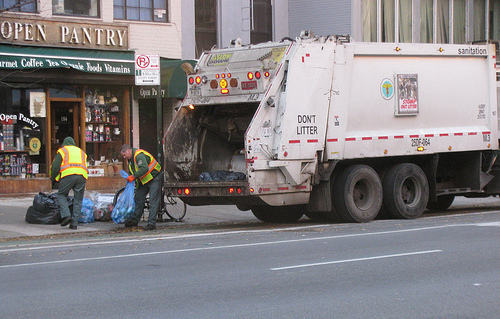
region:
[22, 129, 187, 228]
two men collecting garbage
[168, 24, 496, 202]
white garbage truck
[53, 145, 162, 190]
men wearing orange and yellow safety vests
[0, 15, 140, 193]
coffe shop in the building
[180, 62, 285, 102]
yellow and red lights on back of truck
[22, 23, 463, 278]
picture taken on a city street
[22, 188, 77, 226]
black garbage bags on sidewalk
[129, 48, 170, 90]
white no parking sign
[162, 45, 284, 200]
garbage compactor on back of garbage truck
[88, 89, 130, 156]
items for sale in store window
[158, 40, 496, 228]
a large white truck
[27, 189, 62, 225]
a large black trash bag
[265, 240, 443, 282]
a long white line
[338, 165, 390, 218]
a wheel of a truck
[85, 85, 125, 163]
a window of a store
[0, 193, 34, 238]
part of a sidewalk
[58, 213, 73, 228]
a man's black shoe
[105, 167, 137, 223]
a blue trash bag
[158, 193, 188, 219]
part of a bike tire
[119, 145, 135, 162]
the head of a man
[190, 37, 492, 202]
a garbage truck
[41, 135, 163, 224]
people picking up garbage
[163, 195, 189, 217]
a bicycle on the street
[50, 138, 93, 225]
a person wearing a yellow vest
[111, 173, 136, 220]
a blue trash bag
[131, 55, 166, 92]
a street sign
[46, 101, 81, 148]
a door of the building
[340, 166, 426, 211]
black tires on the garbage truck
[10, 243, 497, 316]
the street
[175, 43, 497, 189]
a large white truck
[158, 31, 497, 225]
old-time trash truck that is loaded in back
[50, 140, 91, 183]
sanitation workers wear yellow safety vests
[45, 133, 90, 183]
this sanitation worker wears a hoodie under his vest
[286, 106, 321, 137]
trash truck has a "don't litter" sign stenciled on the side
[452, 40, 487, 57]
the truck identifies itself as a sanitation truck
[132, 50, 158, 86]
no parking sign next to the trash truck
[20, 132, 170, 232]
the workers collect trash left out for them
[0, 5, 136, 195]
the shop is called Open Pantry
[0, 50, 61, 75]
the Open Pantry serves gourmet coffee and tea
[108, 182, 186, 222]
bicycle parked near the trash truck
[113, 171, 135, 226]
full blue trashbag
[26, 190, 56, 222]
full black trashbag on curb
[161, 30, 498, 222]
large white city garbage truck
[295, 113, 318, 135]
black lettering DON'T LITTER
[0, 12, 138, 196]
Open Pantry coffee shop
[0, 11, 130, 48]
sign OPEN PANTRY above business's doorway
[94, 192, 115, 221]
silver trash can knocked over on sidewalk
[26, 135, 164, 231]
two garbagemen collecting trash bags from sidewalk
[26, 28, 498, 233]
garbagement in yellow vests grab garbage to throw in truck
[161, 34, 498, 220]
A white trash truck.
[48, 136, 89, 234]
A man in a reflective safety vest.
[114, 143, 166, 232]
A man holding a blue trash bag.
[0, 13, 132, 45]
A sign on a building.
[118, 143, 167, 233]
A man in a safety jacket.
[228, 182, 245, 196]
Lights on a truck.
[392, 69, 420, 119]
A painting on a truck.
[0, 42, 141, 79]
A green store front banner.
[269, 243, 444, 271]
A line on a paved road.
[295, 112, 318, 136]
black don't litter sign on dumptruck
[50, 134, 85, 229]
man in green jumpsuit wears yellow safety vest